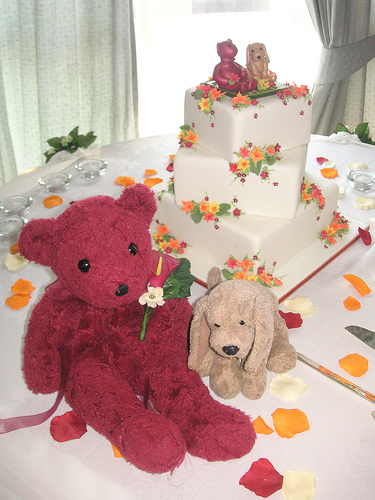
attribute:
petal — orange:
[335, 350, 370, 377]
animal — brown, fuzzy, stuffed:
[184, 281, 295, 397]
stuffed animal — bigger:
[49, 202, 159, 342]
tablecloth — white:
[320, 412, 350, 465]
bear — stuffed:
[19, 183, 255, 475]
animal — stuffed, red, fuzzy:
[24, 146, 271, 482]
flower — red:
[246, 450, 284, 497]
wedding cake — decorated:
[151, 39, 371, 288]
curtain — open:
[296, 7, 374, 127]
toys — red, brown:
[185, 277, 297, 400]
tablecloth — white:
[110, 144, 164, 164]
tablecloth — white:
[325, 137, 366, 158]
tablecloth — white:
[308, 281, 342, 301]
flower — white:
[223, 146, 277, 180]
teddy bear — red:
[51, 199, 190, 385]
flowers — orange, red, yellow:
[176, 196, 236, 230]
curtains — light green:
[5, 16, 135, 182]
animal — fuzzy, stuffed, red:
[14, 179, 258, 473]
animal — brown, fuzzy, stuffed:
[189, 275, 301, 408]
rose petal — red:
[236, 458, 283, 498]